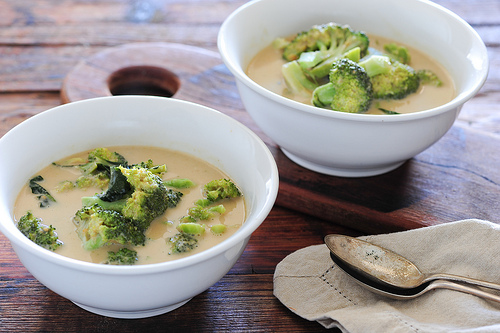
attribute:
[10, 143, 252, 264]
soup — creamy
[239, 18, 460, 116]
soup — creamy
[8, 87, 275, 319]
bowl — small, white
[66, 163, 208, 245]
sauce — white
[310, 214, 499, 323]
spoon — dirty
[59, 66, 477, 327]
table top — wooden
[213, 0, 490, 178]
bowl — small, white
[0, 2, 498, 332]
table — wooden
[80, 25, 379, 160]
bowl — small, white